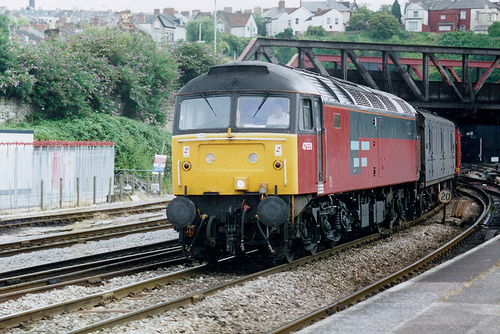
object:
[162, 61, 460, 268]
train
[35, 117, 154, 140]
bush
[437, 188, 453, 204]
numbers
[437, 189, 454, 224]
sign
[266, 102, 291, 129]
man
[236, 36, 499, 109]
bridge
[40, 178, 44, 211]
post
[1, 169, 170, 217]
fence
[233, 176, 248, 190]
light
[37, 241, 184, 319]
tracks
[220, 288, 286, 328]
stones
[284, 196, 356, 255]
wheels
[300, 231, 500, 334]
platform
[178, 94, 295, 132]
window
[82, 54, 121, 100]
flowers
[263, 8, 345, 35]
house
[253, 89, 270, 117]
wiper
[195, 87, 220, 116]
wiper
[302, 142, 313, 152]
sticker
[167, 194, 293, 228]
bumper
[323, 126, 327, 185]
rail